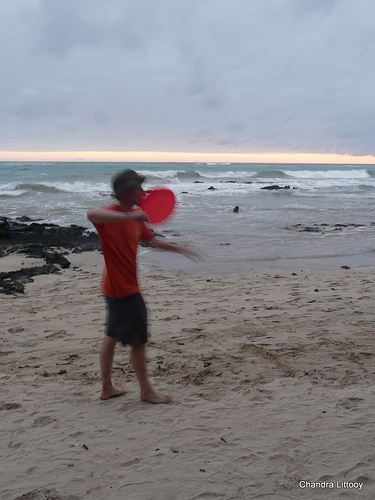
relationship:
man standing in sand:
[77, 177, 176, 398] [218, 345, 276, 392]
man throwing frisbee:
[77, 177, 176, 398] [142, 187, 167, 223]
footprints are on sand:
[159, 342, 295, 386] [218, 345, 276, 392]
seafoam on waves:
[62, 180, 93, 194] [272, 194, 314, 219]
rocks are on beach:
[20, 236, 52, 260] [209, 311, 336, 414]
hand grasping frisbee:
[121, 208, 146, 228] [142, 187, 167, 223]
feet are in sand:
[101, 382, 159, 405] [218, 345, 276, 392]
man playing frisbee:
[77, 177, 176, 398] [142, 187, 167, 223]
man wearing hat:
[77, 177, 176, 398] [112, 166, 144, 187]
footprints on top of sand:
[159, 342, 295, 386] [218, 345, 276, 392]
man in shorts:
[77, 177, 176, 398] [105, 295, 143, 337]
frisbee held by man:
[142, 187, 167, 223] [77, 177, 176, 398]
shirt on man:
[101, 236, 137, 294] [77, 177, 176, 398]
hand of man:
[121, 208, 146, 228] [77, 177, 176, 398]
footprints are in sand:
[159, 342, 295, 386] [218, 345, 276, 392]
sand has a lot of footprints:
[218, 345, 276, 392] [159, 342, 295, 386]